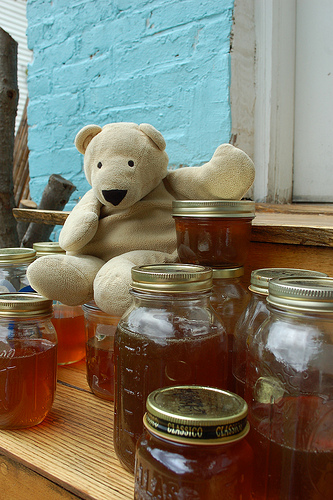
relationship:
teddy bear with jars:
[26, 122, 256, 315] [0, 200, 319, 491]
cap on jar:
[168, 196, 257, 218] [171, 213, 253, 270]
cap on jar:
[0, 244, 36, 269] [0, 265, 35, 299]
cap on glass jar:
[0, 289, 55, 318] [0, 292, 58, 431]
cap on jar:
[130, 260, 215, 296] [110, 288, 229, 476]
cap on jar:
[141, 385, 251, 446] [128, 421, 255, 499]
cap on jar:
[265, 274, 331, 315] [244, 306, 331, 497]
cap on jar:
[246, 266, 330, 296] [231, 288, 273, 410]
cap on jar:
[205, 263, 241, 280] [209, 280, 256, 391]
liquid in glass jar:
[8, 351, 59, 402] [0, 292, 58, 431]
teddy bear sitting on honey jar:
[26, 122, 256, 315] [116, 263, 234, 471]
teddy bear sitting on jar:
[26, 122, 256, 315] [170, 199, 256, 270]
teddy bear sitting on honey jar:
[26, 122, 256, 315] [258, 281, 332, 484]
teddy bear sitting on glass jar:
[26, 122, 256, 315] [0, 292, 58, 431]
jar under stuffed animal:
[77, 296, 115, 400] [52, 108, 217, 315]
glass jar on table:
[4, 288, 71, 415] [0, 323, 288, 491]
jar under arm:
[168, 192, 256, 269] [173, 145, 252, 200]